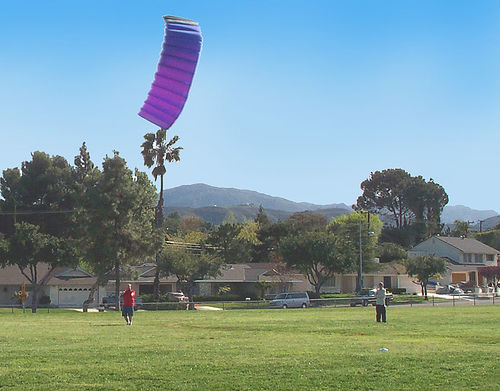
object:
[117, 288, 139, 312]
shirt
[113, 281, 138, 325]
man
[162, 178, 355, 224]
mountain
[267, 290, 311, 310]
van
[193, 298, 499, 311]
street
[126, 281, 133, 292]
head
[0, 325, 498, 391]
grass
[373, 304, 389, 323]
pants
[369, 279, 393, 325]
man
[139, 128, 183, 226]
palm tree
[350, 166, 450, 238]
tree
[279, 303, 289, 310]
front tire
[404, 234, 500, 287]
house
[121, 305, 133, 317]
shorts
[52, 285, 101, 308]
garage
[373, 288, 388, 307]
shirt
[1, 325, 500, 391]
field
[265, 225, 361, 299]
trees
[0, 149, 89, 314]
tree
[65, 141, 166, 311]
tree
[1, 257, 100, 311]
home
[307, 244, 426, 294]
houses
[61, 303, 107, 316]
driveway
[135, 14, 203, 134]
kite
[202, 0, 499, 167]
sky